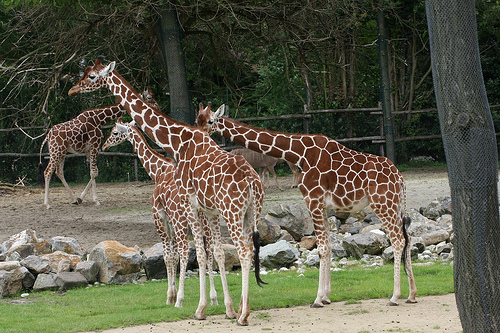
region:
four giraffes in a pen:
[33, 50, 431, 327]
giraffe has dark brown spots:
[190, 95, 435, 311]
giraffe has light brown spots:
[100, 113, 233, 323]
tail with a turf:
[394, 173, 419, 278]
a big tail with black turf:
[248, 182, 273, 299]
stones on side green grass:
[1, 199, 453, 293]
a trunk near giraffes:
[421, 0, 498, 327]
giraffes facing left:
[67, 60, 424, 323]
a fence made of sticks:
[307, 99, 444, 154]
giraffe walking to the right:
[36, 88, 159, 210]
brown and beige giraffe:
[270, 108, 422, 313]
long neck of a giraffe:
[226, 123, 306, 153]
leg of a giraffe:
[380, 227, 406, 310]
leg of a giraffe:
[310, 201, 326, 321]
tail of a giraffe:
[250, 180, 275, 293]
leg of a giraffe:
[226, 225, 252, 330]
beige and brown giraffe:
[20, 116, 106, 209]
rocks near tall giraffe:
[30, 236, 143, 291]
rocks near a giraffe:
[412, 211, 445, 257]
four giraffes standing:
[22, 50, 426, 312]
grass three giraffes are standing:
[10, 259, 442, 332]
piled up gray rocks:
[11, 198, 454, 286]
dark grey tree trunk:
[423, 10, 498, 324]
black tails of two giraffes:
[247, 222, 416, 271]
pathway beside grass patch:
[109, 295, 460, 330]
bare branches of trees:
[11, 8, 440, 101]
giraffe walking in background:
[36, 81, 162, 210]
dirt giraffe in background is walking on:
[13, 156, 336, 264]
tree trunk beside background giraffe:
[154, 8, 194, 123]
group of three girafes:
[74, 58, 431, 326]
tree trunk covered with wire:
[426, 0, 498, 331]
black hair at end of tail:
[248, 228, 281, 295]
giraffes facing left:
[60, 54, 423, 324]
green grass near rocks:
[1, 264, 464, 331]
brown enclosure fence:
[2, 100, 494, 167]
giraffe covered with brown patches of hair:
[191, 100, 420, 309]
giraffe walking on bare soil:
[2, 88, 452, 250]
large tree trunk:
[150, 2, 211, 184]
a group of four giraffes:
[17, 38, 440, 323]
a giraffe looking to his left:
[65, 56, 257, 328]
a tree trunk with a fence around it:
[421, 2, 498, 329]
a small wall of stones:
[0, 194, 475, 296]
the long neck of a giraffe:
[189, 93, 304, 171]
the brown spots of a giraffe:
[304, 143, 362, 197]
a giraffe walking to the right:
[32, 85, 161, 207]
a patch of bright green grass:
[1, 256, 455, 331]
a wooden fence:
[0, 103, 443, 188]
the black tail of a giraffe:
[249, 225, 269, 290]